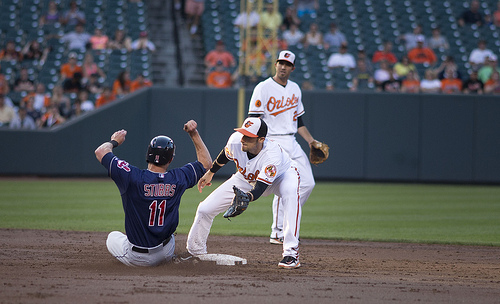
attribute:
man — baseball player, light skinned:
[197, 108, 299, 270]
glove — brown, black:
[227, 185, 247, 218]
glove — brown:
[310, 142, 328, 166]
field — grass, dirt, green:
[3, 178, 496, 301]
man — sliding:
[93, 116, 211, 269]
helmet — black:
[145, 134, 174, 167]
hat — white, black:
[235, 119, 266, 139]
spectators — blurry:
[62, 25, 150, 51]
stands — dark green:
[2, 2, 500, 183]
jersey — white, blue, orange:
[252, 81, 303, 134]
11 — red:
[149, 202, 167, 227]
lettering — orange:
[268, 98, 299, 112]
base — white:
[203, 251, 249, 268]